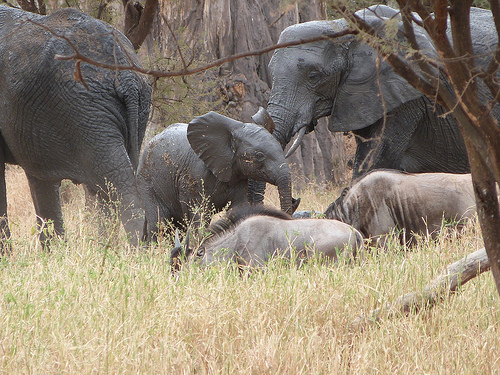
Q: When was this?
A: Daytime.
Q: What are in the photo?
A: Animals.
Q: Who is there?
A: No one.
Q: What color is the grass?
A: Pale yellow.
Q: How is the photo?
A: Clear.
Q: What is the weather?
A: Sunny.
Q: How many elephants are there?
A: Three.